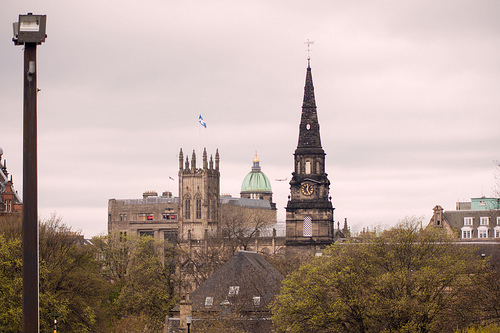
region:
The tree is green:
[304, 233, 386, 315]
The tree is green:
[335, 155, 437, 289]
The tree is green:
[320, 208, 448, 325]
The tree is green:
[330, 263, 430, 330]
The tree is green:
[358, 285, 425, 330]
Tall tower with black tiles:
[266, 39, 342, 275]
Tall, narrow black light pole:
[1, 5, 71, 331]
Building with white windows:
[451, 206, 498, 258]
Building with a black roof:
[178, 218, 283, 316]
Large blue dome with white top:
[239, 146, 275, 200]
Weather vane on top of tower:
[291, 29, 317, 62]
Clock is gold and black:
[293, 172, 322, 202]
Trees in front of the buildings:
[75, 216, 456, 320]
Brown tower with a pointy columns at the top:
[169, 138, 228, 321]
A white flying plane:
[263, 166, 296, 196]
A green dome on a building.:
[235, 150, 281, 207]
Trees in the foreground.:
[270, 218, 495, 329]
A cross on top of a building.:
[290, 30, 325, 61]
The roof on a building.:
[181, 248, 297, 309]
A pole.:
[5, 40, 53, 331]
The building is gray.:
[85, 150, 287, 330]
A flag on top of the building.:
[185, 106, 216, 161]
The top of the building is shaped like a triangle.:
[285, 68, 332, 163]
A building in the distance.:
[405, 156, 498, 268]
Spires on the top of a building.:
[169, 139, 224, 180]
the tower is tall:
[287, 82, 330, 244]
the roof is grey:
[202, 256, 279, 316]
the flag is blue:
[194, 113, 209, 129]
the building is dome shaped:
[246, 165, 271, 197]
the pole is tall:
[10, 18, 62, 330]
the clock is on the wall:
[286, 185, 327, 200]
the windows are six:
[457, 215, 498, 234]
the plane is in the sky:
[275, 172, 292, 184]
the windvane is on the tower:
[291, 33, 322, 65]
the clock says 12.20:
[297, 175, 327, 202]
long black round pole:
[21, 44, 40, 331]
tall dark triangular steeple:
[293, 55, 326, 156]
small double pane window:
[461, 225, 473, 240]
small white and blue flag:
[195, 113, 206, 124]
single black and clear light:
[14, 12, 46, 43]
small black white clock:
[298, 181, 314, 196]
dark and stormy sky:
[1, 0, 499, 237]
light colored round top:
[238, 170, 273, 191]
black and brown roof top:
[166, 250, 288, 315]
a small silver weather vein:
[303, 37, 313, 59]